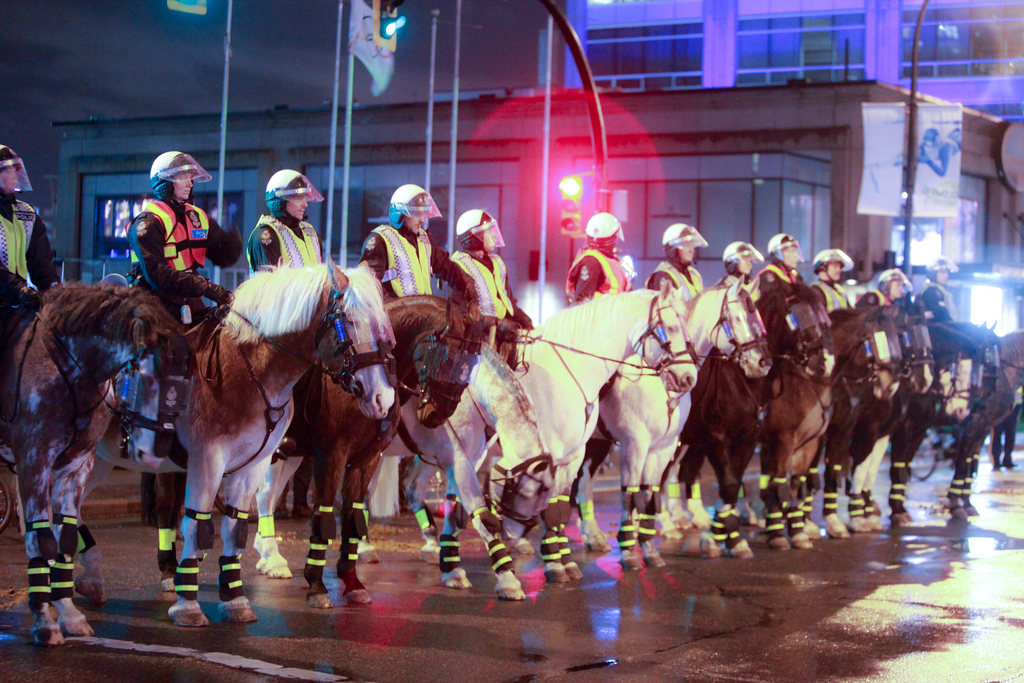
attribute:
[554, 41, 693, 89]
windows — glass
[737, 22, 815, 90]
windows — glass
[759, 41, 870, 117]
windows — glass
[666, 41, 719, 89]
windows — glass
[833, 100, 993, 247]
sign — square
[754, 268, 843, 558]
horse — brown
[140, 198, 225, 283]
vest — orange, yellow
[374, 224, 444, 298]
stripes — yellow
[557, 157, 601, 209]
light — shining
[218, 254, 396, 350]
hair — white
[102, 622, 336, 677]
line — white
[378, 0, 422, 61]
traffic light — green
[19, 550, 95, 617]
strip — yellow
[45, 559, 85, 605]
strip — yellow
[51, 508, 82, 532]
strip — yellow, reflective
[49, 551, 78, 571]
strip — reflective, yellow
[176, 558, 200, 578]
strip — yellow, reflecting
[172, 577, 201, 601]
strip — reflecting, yellow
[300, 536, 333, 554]
strip — yellow, reflecting